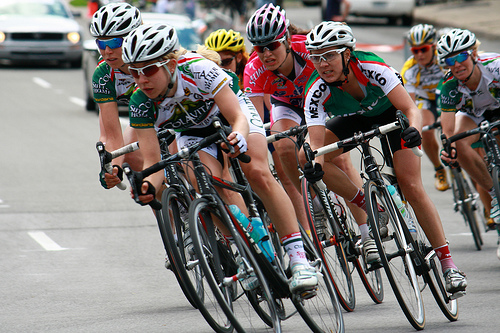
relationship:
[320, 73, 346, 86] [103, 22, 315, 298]
chin on woman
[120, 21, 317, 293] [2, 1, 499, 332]
bike racer cycling in road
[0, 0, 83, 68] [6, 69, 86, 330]
car in street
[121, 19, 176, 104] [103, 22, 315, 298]
head of woman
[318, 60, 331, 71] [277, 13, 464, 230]
nose of woman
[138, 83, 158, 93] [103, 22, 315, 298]
lips of a woman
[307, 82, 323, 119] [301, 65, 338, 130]
mexico on jersey sleeve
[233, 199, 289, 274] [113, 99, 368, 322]
bottles on bicycle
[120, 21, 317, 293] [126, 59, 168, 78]
bike racer wearing sunglasses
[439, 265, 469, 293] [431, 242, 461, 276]
shoe with sock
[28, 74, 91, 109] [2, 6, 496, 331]
markings on road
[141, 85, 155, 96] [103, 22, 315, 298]
mouth of woman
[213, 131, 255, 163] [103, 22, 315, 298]
hand of woman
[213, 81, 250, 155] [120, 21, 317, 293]
arm of bike racer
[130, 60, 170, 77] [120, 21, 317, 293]
sunglasses on bike racer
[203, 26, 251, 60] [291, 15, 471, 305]
helmet on rider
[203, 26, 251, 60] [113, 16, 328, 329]
helmet on rider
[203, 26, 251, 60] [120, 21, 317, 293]
helmet on bike racer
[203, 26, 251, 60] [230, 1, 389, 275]
helmet on rider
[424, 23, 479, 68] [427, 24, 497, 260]
helmet on rider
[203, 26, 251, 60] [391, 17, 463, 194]
helmet on rider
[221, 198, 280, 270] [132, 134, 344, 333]
water bottle on bicycle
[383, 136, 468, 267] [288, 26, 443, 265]
leg of a woman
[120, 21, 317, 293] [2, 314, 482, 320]
bike racer cycling on asphalt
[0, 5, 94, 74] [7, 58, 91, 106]
car switching lanes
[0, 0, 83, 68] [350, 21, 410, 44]
car on road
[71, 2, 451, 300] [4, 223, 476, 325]
bicycle races leaning into turn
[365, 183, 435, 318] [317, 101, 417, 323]
wheel of bike